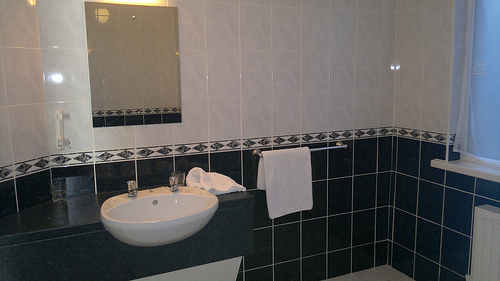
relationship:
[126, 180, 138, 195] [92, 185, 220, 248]
water handle on sink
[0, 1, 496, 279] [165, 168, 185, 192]
bathroom has faucet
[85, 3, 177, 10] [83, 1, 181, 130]
light over mirror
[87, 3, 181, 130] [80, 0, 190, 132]
reflection on mirror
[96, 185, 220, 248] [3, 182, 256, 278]
sink in gray vanity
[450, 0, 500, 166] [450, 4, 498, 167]
curtain on window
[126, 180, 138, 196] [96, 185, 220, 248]
water handle on sink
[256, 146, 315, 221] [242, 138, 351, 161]
towel folded over rack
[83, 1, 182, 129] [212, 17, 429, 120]
mirror on wall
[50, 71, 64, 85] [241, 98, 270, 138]
reflection in tile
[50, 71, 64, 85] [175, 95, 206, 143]
reflection in tile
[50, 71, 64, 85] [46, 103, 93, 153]
reflection in tile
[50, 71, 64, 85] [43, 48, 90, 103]
reflection in tile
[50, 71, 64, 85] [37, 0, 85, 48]
reflection in tile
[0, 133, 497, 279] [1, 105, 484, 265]
black tile on lower wall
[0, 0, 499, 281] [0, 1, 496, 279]
tile on wall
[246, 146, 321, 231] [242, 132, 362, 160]
towel on rack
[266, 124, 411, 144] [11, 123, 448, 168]
shapes on border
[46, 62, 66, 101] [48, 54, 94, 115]
light reflecting off tile